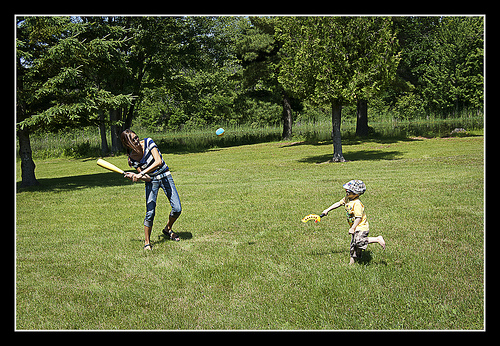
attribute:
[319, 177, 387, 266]
kid — playing baseball, small, playing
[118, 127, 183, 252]
woman — playing baseball, playing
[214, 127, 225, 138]
ball — in mid air, blue, in the air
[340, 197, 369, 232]
shirt — yellow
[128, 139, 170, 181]
shirt — striped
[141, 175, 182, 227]
jeans — blue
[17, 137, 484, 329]
grass — green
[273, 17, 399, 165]
tree — large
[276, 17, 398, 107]
leaves — green